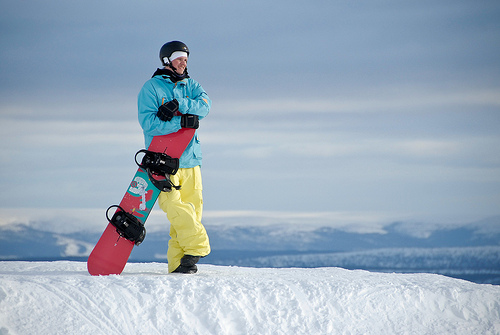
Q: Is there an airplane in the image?
A: No, there are no airplanes.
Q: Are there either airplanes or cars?
A: No, there are no airplanes or cars.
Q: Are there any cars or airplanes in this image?
A: No, there are no airplanes or cars.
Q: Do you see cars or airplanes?
A: No, there are no airplanes or cars.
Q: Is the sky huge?
A: Yes, the sky is huge.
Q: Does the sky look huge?
A: Yes, the sky is huge.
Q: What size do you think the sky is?
A: The sky is huge.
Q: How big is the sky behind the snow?
A: The sky is huge.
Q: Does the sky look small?
A: No, the sky is huge.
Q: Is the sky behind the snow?
A: Yes, the sky is behind the snow.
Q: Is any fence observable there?
A: No, there are no fences.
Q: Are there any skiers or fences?
A: No, there are no fences or skiers.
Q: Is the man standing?
A: Yes, the man is standing.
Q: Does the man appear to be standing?
A: Yes, the man is standing.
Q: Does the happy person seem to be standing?
A: Yes, the man is standing.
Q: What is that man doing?
A: The man is standing.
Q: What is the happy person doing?
A: The man is standing.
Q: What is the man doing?
A: The man is standing.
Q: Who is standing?
A: The man is standing.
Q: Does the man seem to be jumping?
A: No, the man is standing.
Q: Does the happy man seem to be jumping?
A: No, the man is standing.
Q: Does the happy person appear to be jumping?
A: No, the man is standing.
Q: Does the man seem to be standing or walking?
A: The man is standing.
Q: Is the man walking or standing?
A: The man is standing.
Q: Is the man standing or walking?
A: The man is standing.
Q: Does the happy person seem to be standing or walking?
A: The man is standing.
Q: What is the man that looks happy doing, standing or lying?
A: The man is standing.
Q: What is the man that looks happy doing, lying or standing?
A: The man is standing.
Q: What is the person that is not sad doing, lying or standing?
A: The man is standing.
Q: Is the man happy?
A: Yes, the man is happy.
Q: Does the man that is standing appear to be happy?
A: Yes, the man is happy.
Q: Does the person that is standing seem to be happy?
A: Yes, the man is happy.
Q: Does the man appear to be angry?
A: No, the man is happy.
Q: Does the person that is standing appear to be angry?
A: No, the man is happy.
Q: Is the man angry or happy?
A: The man is happy.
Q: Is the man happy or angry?
A: The man is happy.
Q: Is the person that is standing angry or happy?
A: The man is happy.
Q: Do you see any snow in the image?
A: Yes, there is snow.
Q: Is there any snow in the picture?
A: Yes, there is snow.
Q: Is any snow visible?
A: Yes, there is snow.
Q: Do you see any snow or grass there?
A: Yes, there is snow.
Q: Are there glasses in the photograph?
A: No, there are no glasses.